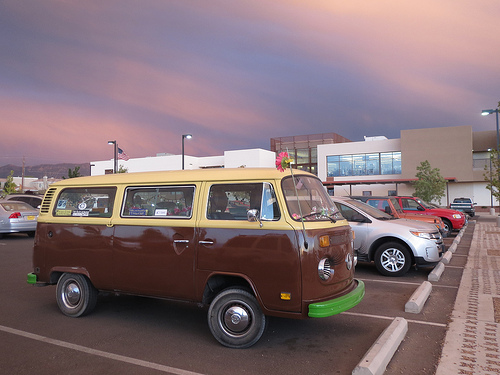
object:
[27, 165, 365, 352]
van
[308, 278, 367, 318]
bumper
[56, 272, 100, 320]
wheels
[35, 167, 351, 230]
light brown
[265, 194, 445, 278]
car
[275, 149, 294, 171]
flower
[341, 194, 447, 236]
car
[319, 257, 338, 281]
headlight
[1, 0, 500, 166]
sky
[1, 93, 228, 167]
clouds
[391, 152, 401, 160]
lights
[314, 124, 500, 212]
building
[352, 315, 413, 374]
block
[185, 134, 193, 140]
light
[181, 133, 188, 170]
pole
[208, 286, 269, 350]
wheel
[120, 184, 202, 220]
window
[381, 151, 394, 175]
window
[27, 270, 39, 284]
bumper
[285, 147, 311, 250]
antenna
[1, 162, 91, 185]
mountain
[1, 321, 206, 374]
line